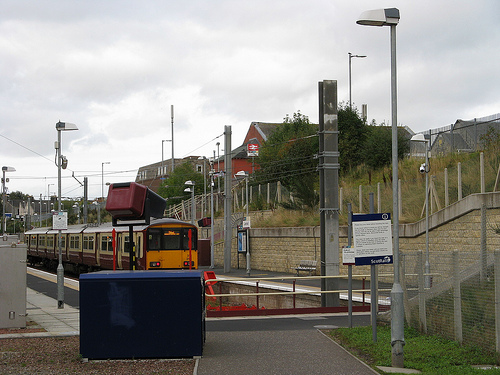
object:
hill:
[249, 147, 499, 229]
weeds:
[250, 147, 500, 227]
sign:
[349, 212, 394, 268]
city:
[0, 7, 499, 374]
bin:
[74, 268, 208, 360]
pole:
[167, 104, 177, 181]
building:
[212, 118, 413, 188]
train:
[16, 215, 200, 273]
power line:
[0, 133, 57, 166]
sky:
[0, 0, 498, 201]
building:
[425, 117, 499, 168]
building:
[133, 153, 210, 201]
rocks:
[0, 330, 196, 374]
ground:
[0, 265, 423, 374]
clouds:
[0, 0, 499, 158]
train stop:
[23, 215, 198, 272]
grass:
[327, 322, 499, 374]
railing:
[204, 272, 442, 321]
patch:
[324, 318, 497, 373]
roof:
[206, 121, 416, 165]